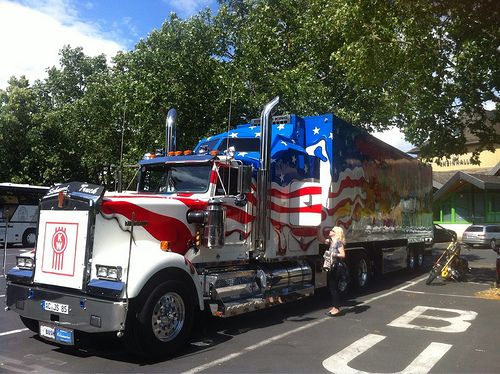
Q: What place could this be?
A: It is a parking lot.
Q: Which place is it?
A: It is a parking lot.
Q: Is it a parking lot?
A: Yes, it is a parking lot.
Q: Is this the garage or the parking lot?
A: It is the parking lot.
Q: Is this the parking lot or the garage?
A: It is the parking lot.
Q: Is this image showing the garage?
A: No, the picture is showing the parking lot.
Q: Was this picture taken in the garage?
A: No, the picture was taken in the parking lot.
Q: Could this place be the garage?
A: No, it is the parking lot.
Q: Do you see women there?
A: Yes, there is a woman.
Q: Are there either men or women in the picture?
A: Yes, there is a woman.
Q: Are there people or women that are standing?
A: Yes, the woman is standing.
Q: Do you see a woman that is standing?
A: Yes, there is a woman that is standing.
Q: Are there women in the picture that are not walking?
A: Yes, there is a woman that is standing.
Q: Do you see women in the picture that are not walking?
A: Yes, there is a woman that is standing .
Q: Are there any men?
A: No, there are no men.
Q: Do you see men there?
A: No, there are no men.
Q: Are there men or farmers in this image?
A: No, there are no men or farmers.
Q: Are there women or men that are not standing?
A: No, there is a woman but she is standing.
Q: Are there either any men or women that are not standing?
A: No, there is a woman but she is standing.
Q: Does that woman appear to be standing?
A: Yes, the woman is standing.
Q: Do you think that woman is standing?
A: Yes, the woman is standing.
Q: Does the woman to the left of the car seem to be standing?
A: Yes, the woman is standing.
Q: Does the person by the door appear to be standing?
A: Yes, the woman is standing.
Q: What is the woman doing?
A: The woman is standing.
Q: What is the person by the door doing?
A: The woman is standing.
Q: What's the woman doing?
A: The woman is standing.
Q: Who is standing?
A: The woman is standing.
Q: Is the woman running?
A: No, the woman is standing.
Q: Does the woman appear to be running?
A: No, the woman is standing.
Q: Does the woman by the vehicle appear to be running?
A: No, the woman is standing.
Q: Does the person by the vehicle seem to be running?
A: No, the woman is standing.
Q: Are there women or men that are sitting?
A: No, there is a woman but she is standing.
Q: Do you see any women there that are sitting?
A: No, there is a woman but she is standing.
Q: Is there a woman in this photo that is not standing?
A: No, there is a woman but she is standing.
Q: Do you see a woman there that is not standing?
A: No, there is a woman but she is standing.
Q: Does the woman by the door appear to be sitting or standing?
A: The woman is standing.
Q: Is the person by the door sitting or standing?
A: The woman is standing.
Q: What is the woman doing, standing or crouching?
A: The woman is standing.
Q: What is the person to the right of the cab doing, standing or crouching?
A: The woman is standing.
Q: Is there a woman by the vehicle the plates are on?
A: Yes, there is a woman by the vehicle.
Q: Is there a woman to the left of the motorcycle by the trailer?
A: Yes, there is a woman to the left of the motorcycle.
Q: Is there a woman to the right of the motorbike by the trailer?
A: No, the woman is to the left of the motorbike.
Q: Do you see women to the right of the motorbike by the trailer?
A: No, the woman is to the left of the motorbike.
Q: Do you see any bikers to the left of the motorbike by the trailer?
A: No, there is a woman to the left of the motorcycle.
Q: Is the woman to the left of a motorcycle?
A: Yes, the woman is to the left of a motorcycle.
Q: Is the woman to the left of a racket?
A: No, the woman is to the left of a motorcycle.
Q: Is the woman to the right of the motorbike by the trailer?
A: No, the woman is to the left of the motorcycle.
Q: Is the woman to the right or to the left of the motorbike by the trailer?
A: The woman is to the left of the motorbike.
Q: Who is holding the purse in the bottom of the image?
A: The woman is holding the purse.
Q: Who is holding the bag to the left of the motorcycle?
A: The woman is holding the purse.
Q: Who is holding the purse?
A: The woman is holding the purse.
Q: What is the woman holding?
A: The woman is holding the purse.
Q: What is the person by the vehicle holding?
A: The woman is holding the purse.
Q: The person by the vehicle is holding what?
A: The woman is holding the purse.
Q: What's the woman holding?
A: The woman is holding the purse.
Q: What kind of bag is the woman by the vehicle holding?
A: The woman is holding the purse.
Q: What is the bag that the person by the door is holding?
A: The bag is a purse.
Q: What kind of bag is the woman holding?
A: The woman is holding the purse.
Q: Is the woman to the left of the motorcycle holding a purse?
A: Yes, the woman is holding a purse.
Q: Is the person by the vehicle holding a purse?
A: Yes, the woman is holding a purse.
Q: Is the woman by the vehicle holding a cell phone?
A: No, the woman is holding a purse.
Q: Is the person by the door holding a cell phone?
A: No, the woman is holding a purse.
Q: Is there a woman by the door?
A: Yes, there is a woman by the door.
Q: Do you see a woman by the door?
A: Yes, there is a woman by the door.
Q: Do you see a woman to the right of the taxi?
A: Yes, there is a woman to the right of the taxi.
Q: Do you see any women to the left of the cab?
A: No, the woman is to the right of the cab.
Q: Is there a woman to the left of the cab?
A: No, the woman is to the right of the cab.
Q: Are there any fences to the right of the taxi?
A: No, there is a woman to the right of the taxi.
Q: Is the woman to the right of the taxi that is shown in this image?
A: Yes, the woman is to the right of the taxi.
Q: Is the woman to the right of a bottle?
A: No, the woman is to the right of the taxi.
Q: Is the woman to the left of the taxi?
A: No, the woman is to the right of the taxi.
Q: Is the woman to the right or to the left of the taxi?
A: The woman is to the right of the taxi.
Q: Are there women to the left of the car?
A: Yes, there is a woman to the left of the car.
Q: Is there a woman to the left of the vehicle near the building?
A: Yes, there is a woman to the left of the car.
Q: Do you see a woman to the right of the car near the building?
A: No, the woman is to the left of the car.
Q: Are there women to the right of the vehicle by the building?
A: No, the woman is to the left of the car.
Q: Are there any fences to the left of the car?
A: No, there is a woman to the left of the car.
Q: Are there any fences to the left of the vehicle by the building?
A: No, there is a woman to the left of the car.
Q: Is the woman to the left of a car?
A: Yes, the woman is to the left of a car.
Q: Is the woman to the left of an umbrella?
A: No, the woman is to the left of a car.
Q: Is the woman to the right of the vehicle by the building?
A: No, the woman is to the left of the car.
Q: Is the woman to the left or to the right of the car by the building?
A: The woman is to the left of the car.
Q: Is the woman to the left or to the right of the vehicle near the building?
A: The woman is to the left of the car.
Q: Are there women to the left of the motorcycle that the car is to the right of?
A: Yes, there is a woman to the left of the motorcycle.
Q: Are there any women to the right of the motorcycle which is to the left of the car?
A: No, the woman is to the left of the motorbike.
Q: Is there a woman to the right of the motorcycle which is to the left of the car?
A: No, the woman is to the left of the motorbike.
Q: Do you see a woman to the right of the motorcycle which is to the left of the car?
A: No, the woman is to the left of the motorbike.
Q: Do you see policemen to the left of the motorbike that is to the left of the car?
A: No, there is a woman to the left of the motorcycle.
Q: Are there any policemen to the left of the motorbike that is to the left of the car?
A: No, there is a woman to the left of the motorcycle.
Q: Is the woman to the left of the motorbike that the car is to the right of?
A: Yes, the woman is to the left of the motorcycle.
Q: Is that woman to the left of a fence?
A: No, the woman is to the left of the motorcycle.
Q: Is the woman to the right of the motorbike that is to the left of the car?
A: No, the woman is to the left of the motorbike.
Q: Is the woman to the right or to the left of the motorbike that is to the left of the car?
A: The woman is to the left of the motorbike.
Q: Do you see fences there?
A: No, there are no fences.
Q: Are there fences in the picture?
A: No, there are no fences.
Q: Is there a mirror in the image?
A: Yes, there is a mirror.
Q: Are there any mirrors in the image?
A: Yes, there is a mirror.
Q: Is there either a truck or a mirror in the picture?
A: Yes, there is a mirror.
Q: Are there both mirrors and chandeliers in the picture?
A: No, there is a mirror but no chandeliers.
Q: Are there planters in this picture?
A: No, there are no planters.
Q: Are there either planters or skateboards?
A: No, there are no planters or skateboards.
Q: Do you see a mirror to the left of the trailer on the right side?
A: Yes, there is a mirror to the left of the trailer.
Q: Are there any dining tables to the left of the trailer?
A: No, there is a mirror to the left of the trailer.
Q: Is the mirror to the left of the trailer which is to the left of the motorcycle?
A: Yes, the mirror is to the left of the trailer.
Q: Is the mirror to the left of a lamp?
A: No, the mirror is to the left of the trailer.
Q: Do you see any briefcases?
A: No, there are no briefcases.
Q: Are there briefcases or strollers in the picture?
A: No, there are no briefcases or strollers.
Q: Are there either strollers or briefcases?
A: No, there are no briefcases or strollers.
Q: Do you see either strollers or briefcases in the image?
A: No, there are no briefcases or strollers.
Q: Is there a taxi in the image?
A: Yes, there is a taxi.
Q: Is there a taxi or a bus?
A: Yes, there is a taxi.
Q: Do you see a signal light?
A: No, there are no traffic lights.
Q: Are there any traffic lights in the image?
A: No, there are no traffic lights.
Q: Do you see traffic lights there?
A: No, there are no traffic lights.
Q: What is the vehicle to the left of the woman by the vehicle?
A: The vehicle is a taxi.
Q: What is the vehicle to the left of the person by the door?
A: The vehicle is a taxi.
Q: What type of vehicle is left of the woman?
A: The vehicle is a taxi.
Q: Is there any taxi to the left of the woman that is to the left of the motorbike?
A: Yes, there is a taxi to the left of the woman.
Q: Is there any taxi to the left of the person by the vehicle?
A: Yes, there is a taxi to the left of the woman.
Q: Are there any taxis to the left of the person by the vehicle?
A: Yes, there is a taxi to the left of the woman.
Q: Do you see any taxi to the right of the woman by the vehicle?
A: No, the taxi is to the left of the woman.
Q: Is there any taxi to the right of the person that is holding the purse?
A: No, the taxi is to the left of the woman.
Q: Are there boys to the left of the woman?
A: No, there is a taxi to the left of the woman.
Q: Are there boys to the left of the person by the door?
A: No, there is a taxi to the left of the woman.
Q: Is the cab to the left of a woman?
A: Yes, the cab is to the left of a woman.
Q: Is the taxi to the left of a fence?
A: No, the taxi is to the left of a woman.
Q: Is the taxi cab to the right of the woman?
A: No, the taxi cab is to the left of the woman.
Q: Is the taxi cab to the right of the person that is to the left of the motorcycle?
A: No, the taxi cab is to the left of the woman.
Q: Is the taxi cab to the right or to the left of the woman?
A: The taxi cab is to the left of the woman.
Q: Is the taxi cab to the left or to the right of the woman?
A: The taxi cab is to the left of the woman.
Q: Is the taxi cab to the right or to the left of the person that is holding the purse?
A: The taxi cab is to the left of the woman.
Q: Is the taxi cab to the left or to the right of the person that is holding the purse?
A: The taxi cab is to the left of the woman.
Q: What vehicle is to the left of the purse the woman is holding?
A: The vehicle is a taxi.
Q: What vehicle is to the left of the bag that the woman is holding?
A: The vehicle is a taxi.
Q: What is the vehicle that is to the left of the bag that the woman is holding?
A: The vehicle is a taxi.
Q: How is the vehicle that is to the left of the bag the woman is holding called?
A: The vehicle is a taxi.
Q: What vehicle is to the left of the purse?
A: The vehicle is a taxi.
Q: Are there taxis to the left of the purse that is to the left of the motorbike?
A: Yes, there is a taxi to the left of the purse.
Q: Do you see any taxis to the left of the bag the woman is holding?
A: Yes, there is a taxi to the left of the purse.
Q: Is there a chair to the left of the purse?
A: No, there is a taxi to the left of the purse.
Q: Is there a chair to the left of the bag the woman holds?
A: No, there is a taxi to the left of the purse.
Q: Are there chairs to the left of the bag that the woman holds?
A: No, there is a taxi to the left of the purse.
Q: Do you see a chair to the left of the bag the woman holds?
A: No, there is a taxi to the left of the purse.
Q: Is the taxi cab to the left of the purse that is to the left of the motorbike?
A: Yes, the taxi cab is to the left of the purse.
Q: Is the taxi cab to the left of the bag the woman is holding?
A: Yes, the taxi cab is to the left of the purse.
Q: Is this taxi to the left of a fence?
A: No, the taxi is to the left of the purse.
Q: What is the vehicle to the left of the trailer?
A: The vehicle is a taxi.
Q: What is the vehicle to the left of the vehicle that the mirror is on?
A: The vehicle is a taxi.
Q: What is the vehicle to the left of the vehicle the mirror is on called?
A: The vehicle is a taxi.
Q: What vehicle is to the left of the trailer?
A: The vehicle is a taxi.